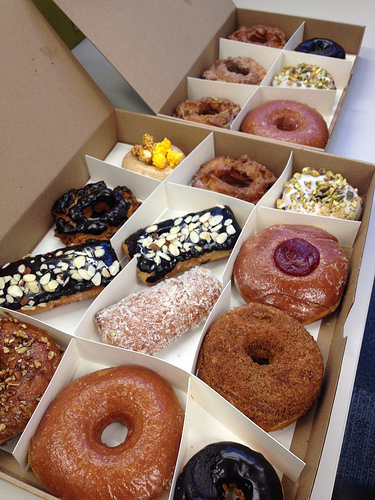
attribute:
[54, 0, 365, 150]
box — edge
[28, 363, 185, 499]
donut — glazed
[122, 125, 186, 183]
donut — yellow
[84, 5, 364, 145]
box — assorted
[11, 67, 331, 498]
box — assorted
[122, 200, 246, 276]
frosting — nut covered, chocolate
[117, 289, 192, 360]
topping — white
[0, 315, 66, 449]
donut — honey, walnut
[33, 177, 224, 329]
doughnuts — different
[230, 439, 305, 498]
donut — chocolate icing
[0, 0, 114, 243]
cover — brown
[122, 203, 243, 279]
rectangular sweets — chocolate, nut flakes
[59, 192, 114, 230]
donut — chocolate topping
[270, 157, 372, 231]
donut — white, dry, pieces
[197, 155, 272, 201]
donut — cream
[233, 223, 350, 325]
donut — glazed, strawberry jam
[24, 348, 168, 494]
donut — glazed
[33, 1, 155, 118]
knife — edge